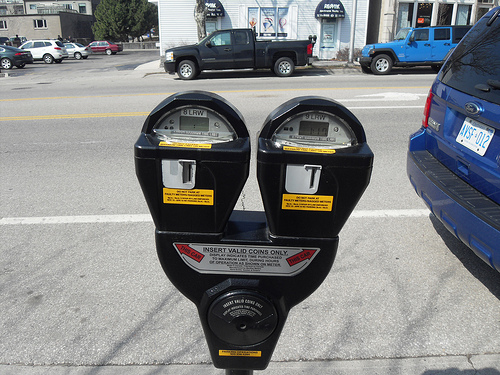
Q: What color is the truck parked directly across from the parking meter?
A: Black.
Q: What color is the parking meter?
A: Black.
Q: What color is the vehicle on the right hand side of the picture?
A: Blue.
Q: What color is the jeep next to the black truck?
A: Blue.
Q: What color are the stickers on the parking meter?
A: Yellow and White.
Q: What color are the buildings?
A: White.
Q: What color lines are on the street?
A: Yellow and White.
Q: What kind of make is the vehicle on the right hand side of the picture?
A: Ford.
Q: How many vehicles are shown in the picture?
A: 7.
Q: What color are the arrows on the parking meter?
A: Red.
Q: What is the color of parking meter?
A: Black, yellow, grey and red.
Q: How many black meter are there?
A: One.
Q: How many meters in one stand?
A: Two.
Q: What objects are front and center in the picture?
A: Parking meters.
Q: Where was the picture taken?
A: A city street.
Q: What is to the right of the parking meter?
A: The back of a vehicle.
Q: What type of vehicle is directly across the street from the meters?
A: Pickup truck.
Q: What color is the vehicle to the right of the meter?
A: Blue.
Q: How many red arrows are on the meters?
A: Two.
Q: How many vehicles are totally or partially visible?
A: Seven.